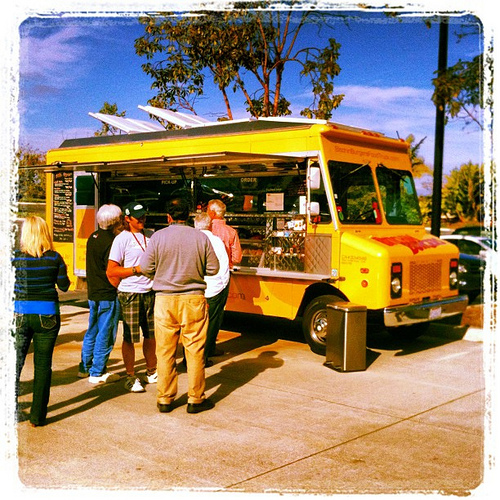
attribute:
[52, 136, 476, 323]
truck — yellow, open, open to people, parked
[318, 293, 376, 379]
trash can — metal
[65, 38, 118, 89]
sky — blue